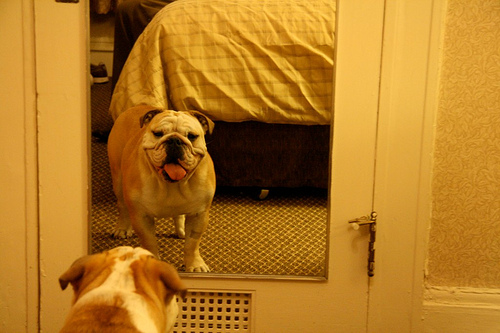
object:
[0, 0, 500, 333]
bedroom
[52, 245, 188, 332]
dog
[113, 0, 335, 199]
bed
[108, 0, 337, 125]
comforter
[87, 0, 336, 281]
mirror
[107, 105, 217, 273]
reflection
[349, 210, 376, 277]
door hinge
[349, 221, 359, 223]
stopper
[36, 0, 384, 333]
door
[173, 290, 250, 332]
vent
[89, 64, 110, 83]
shoes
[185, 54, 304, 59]
lines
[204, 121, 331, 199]
bottom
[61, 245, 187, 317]
head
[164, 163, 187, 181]
tongue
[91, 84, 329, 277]
carpet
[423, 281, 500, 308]
moulding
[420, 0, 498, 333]
wall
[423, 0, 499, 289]
wallpaper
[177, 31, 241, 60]
pattern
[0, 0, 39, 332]
doorframe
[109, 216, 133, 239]
paws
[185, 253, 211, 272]
paws